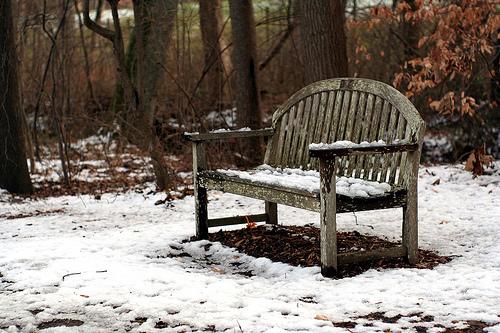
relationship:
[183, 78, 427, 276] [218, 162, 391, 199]
bench with snow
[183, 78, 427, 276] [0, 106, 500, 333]
bench in middle of ground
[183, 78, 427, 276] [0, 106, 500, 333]
bench out in ground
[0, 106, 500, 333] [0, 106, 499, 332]
ground fallen on ground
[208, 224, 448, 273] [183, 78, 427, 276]
leaves under bench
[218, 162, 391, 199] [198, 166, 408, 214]
snow on top of seat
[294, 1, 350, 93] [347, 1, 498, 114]
tree with leaves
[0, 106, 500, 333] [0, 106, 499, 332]
ground on top of ground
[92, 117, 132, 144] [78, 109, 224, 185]
branch on top of bush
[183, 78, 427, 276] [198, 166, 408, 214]
bench has seat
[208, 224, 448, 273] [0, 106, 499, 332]
leaves on top of ground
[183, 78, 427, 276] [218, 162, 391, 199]
bench covered in snow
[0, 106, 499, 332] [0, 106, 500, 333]
ground covered in ground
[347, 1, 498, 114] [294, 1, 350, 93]
leaves on side of tree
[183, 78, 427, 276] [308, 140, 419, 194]
bench has arm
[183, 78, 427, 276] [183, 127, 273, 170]
bench has arm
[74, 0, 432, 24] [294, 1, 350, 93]
stream running behind tree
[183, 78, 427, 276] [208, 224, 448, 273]
bench covering leaves